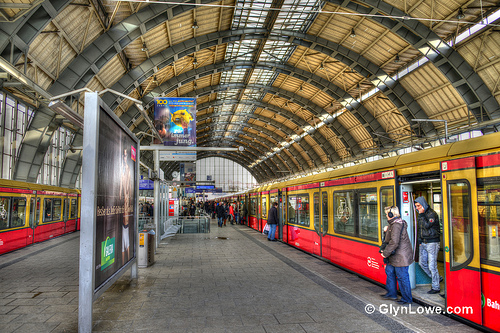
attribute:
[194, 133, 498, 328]
train — yellow, red, gold, long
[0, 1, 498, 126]
domed ceiling — high domed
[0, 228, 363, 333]
floor — grey, cement bricks, gray, brick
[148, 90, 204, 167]
sign — colorful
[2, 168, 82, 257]
train — red, yellow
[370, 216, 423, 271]
jacket — brown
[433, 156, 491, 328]
door — sliding